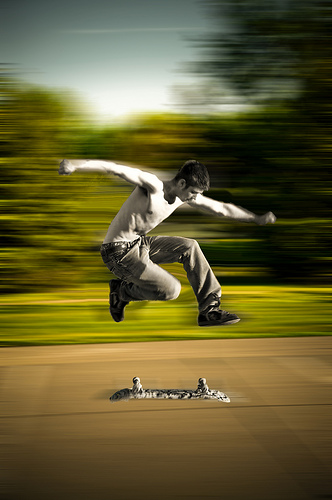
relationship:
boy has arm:
[41, 136, 292, 348] [182, 191, 284, 230]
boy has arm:
[41, 136, 292, 348] [54, 154, 157, 193]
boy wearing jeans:
[58, 158, 277, 327] [100, 233, 222, 311]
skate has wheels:
[108, 376, 231, 405] [131, 373, 143, 386]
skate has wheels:
[108, 376, 231, 405] [197, 373, 207, 386]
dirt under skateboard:
[34, 419, 274, 491] [110, 373, 237, 411]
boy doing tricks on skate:
[58, 158, 277, 327] [108, 376, 231, 405]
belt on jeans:
[86, 244, 139, 255] [97, 220, 233, 306]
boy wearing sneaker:
[58, 158, 277, 327] [196, 309, 240, 326]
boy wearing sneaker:
[58, 158, 277, 327] [106, 277, 132, 322]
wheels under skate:
[196, 377, 209, 388] [111, 379, 233, 401]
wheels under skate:
[129, 375, 143, 388] [111, 379, 233, 401]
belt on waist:
[100, 242, 129, 256] [99, 225, 167, 254]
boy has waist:
[58, 158, 277, 327] [99, 225, 167, 254]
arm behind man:
[51, 150, 149, 191] [52, 142, 282, 330]